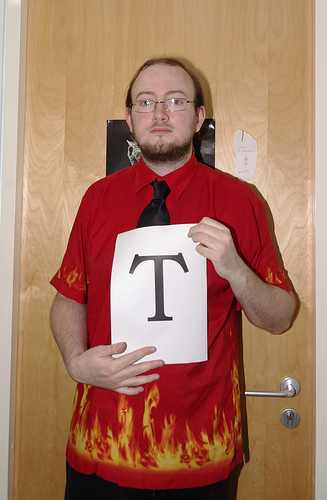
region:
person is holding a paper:
[95, 209, 235, 400]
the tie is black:
[135, 174, 179, 226]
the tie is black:
[125, 167, 182, 251]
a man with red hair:
[120, 41, 241, 204]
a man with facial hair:
[96, 39, 235, 194]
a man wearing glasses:
[103, 53, 221, 168]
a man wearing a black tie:
[126, 63, 218, 235]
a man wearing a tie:
[86, 41, 226, 228]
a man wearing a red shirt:
[85, 47, 269, 332]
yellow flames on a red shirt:
[60, 386, 251, 498]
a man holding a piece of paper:
[107, 67, 272, 370]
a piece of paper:
[81, 194, 251, 388]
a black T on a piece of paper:
[82, 227, 216, 384]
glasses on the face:
[121, 92, 207, 122]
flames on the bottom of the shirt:
[59, 369, 259, 489]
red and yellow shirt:
[46, 162, 281, 490]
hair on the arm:
[48, 293, 94, 362]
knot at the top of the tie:
[147, 177, 171, 207]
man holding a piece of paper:
[41, 43, 300, 497]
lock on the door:
[277, 408, 303, 429]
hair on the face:
[125, 118, 203, 167]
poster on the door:
[100, 110, 223, 182]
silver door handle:
[239, 371, 309, 403]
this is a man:
[42, 38, 319, 498]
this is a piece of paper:
[87, 183, 228, 391]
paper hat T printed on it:
[87, 206, 233, 397]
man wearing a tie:
[110, 156, 229, 305]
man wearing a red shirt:
[62, 162, 301, 482]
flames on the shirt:
[57, 345, 257, 492]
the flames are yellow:
[56, 348, 245, 486]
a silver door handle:
[223, 337, 312, 450]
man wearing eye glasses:
[138, 85, 222, 151]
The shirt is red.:
[183, 184, 238, 212]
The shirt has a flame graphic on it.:
[175, 407, 228, 468]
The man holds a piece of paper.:
[82, 214, 231, 397]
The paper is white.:
[169, 322, 203, 352]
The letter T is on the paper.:
[127, 252, 188, 321]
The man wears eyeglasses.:
[131, 98, 198, 112]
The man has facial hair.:
[143, 144, 187, 162]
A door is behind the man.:
[24, 0, 312, 52]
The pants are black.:
[72, 480, 102, 498]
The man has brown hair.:
[146, 58, 176, 64]